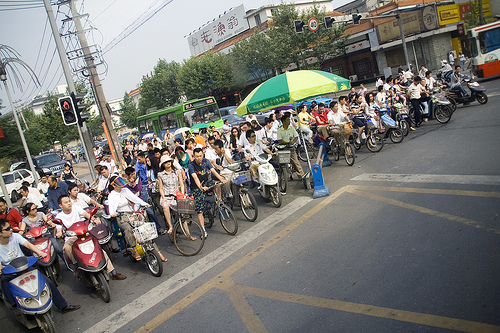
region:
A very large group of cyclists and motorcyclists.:
[0, 57, 490, 329]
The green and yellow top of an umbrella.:
[248, 70, 350, 94]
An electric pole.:
[80, 0, 120, 135]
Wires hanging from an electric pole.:
[104, 0, 174, 50]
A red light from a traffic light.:
[57, 92, 92, 125]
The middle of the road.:
[269, 211, 496, 331]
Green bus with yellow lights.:
[179, 103, 223, 123]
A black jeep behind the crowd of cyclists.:
[36, 153, 65, 170]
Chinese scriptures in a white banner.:
[208, 18, 246, 32]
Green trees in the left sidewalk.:
[147, 62, 237, 94]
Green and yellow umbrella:
[249, 77, 340, 115]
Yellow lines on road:
[232, 259, 297, 331]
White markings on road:
[150, 270, 225, 285]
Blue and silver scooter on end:
[8, 252, 76, 330]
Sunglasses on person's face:
[3, 222, 20, 240]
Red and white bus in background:
[466, 16, 488, 57]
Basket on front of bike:
[170, 188, 227, 227]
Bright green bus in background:
[136, 77, 249, 146]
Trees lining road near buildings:
[128, 60, 356, 97]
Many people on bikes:
[48, 124, 365, 228]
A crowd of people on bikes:
[15, 50, 499, 297]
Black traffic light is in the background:
[53, 91, 95, 134]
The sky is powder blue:
[8, 8, 190, 89]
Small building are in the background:
[220, 6, 499, 81]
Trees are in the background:
[136, 45, 241, 121]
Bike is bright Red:
[46, 213, 135, 303]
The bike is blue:
[6, 244, 79, 327]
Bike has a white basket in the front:
[119, 208, 170, 258]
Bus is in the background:
[461, 8, 499, 85]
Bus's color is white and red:
[450, 15, 499, 94]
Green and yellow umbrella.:
[234, 69, 351, 117]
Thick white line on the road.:
[347, 172, 499, 183]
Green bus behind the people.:
[132, 95, 220, 139]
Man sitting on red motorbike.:
[54, 195, 129, 282]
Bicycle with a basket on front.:
[155, 193, 207, 258]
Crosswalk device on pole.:
[57, 97, 77, 126]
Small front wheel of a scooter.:
[145, 248, 162, 276]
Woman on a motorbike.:
[17, 201, 65, 282]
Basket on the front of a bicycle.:
[173, 197, 195, 214]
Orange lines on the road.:
[347, 183, 498, 235]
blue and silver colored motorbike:
[3, 252, 62, 331]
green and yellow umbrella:
[236, 65, 354, 199]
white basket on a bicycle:
[128, 219, 161, 245]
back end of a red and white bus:
[465, 22, 499, 84]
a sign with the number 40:
[307, 16, 322, 33]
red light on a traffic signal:
[54, 93, 77, 127]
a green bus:
[131, 91, 223, 134]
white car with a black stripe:
[1, 165, 38, 197]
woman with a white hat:
[155, 152, 190, 232]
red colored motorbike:
[48, 212, 116, 304]